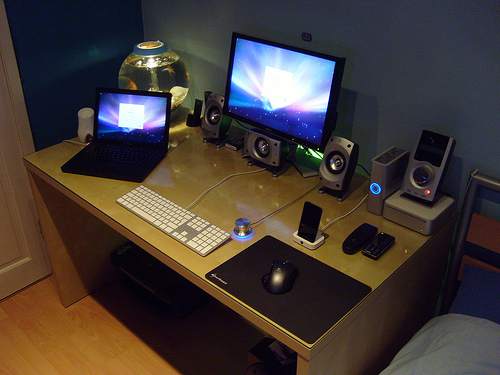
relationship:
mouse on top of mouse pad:
[263, 257, 298, 295] [203, 234, 371, 346]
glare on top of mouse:
[270, 269, 285, 287] [263, 257, 298, 295]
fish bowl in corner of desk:
[118, 38, 191, 113] [22, 104, 458, 373]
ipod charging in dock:
[296, 198, 323, 241] [292, 226, 325, 250]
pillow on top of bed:
[444, 263, 499, 326] [375, 167, 499, 374]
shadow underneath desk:
[32, 172, 297, 374] [22, 104, 458, 373]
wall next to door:
[3, 0, 145, 151] [1, 57, 49, 308]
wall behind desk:
[142, 1, 499, 217] [22, 104, 458, 373]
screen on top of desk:
[227, 38, 336, 143] [22, 104, 458, 373]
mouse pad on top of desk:
[203, 234, 371, 346] [22, 104, 458, 373]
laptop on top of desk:
[61, 87, 171, 184] [22, 104, 458, 373]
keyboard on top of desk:
[116, 184, 231, 256] [22, 104, 458, 373]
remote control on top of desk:
[340, 219, 378, 254] [22, 104, 458, 373]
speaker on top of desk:
[198, 89, 231, 148] [22, 104, 458, 373]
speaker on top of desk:
[314, 135, 359, 201] [22, 104, 458, 373]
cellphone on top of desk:
[361, 230, 396, 259] [22, 104, 458, 373]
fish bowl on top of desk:
[118, 38, 191, 113] [22, 104, 458, 373]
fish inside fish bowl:
[163, 63, 176, 78] [118, 38, 191, 113]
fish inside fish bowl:
[121, 71, 137, 91] [118, 38, 191, 113]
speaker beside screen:
[198, 89, 231, 148] [227, 38, 336, 143]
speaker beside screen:
[314, 135, 359, 201] [227, 38, 336, 143]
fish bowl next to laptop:
[118, 38, 191, 113] [61, 87, 171, 184]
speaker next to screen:
[198, 89, 231, 148] [227, 38, 336, 143]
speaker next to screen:
[314, 135, 359, 201] [227, 38, 336, 143]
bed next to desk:
[375, 167, 499, 374] [22, 104, 458, 373]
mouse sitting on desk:
[263, 257, 298, 295] [22, 104, 458, 373]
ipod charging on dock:
[296, 198, 323, 241] [292, 226, 325, 250]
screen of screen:
[227, 38, 336, 143] [227, 38, 336, 143]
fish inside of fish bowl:
[163, 63, 176, 78] [118, 38, 191, 113]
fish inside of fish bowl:
[121, 71, 137, 91] [118, 38, 191, 113]